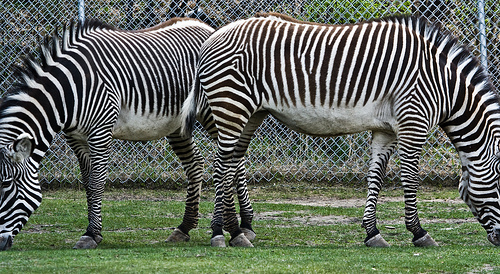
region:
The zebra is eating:
[190, 13, 499, 255]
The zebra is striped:
[187, 7, 497, 270]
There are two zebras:
[1, 1, 498, 269]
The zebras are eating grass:
[3, 3, 499, 272]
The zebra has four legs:
[194, 5, 498, 260]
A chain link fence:
[3, 9, 498, 185]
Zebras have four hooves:
[206, 206, 457, 261]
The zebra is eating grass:
[1, 28, 222, 272]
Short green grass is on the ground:
[7, 185, 496, 267]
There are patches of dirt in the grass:
[254, 177, 351, 270]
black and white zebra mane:
[1, 6, 123, 120]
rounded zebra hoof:
[73, 225, 101, 252]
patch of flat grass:
[274, 238, 348, 265]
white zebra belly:
[256, 88, 384, 152]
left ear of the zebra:
[12, 129, 41, 162]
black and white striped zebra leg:
[200, 106, 240, 248]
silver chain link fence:
[10, 5, 40, 37]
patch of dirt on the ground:
[278, 190, 356, 214]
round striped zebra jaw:
[4, 183, 49, 243]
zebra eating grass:
[0, 2, 242, 254]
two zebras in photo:
[6, 3, 499, 255]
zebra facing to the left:
[2, 132, 54, 254]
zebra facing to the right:
[458, 127, 498, 247]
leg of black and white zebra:
[81, 185, 116, 254]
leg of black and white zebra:
[183, 193, 200, 247]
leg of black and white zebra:
[221, 201, 255, 262]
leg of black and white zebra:
[357, 197, 393, 256]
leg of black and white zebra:
[398, 203, 443, 254]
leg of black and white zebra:
[241, 193, 268, 241]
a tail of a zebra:
[169, 70, 208, 145]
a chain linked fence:
[265, 132, 348, 188]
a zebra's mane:
[385, 11, 498, 133]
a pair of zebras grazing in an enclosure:
[0, 2, 495, 251]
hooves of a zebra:
[151, 220, 310, 260]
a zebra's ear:
[3, 127, 64, 165]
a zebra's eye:
[0, 167, 32, 204]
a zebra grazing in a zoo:
[1, 3, 159, 272]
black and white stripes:
[244, 34, 406, 114]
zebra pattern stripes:
[90, 42, 306, 114]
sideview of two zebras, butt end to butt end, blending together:
[0, 12, 498, 255]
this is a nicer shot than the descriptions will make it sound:
[0, 1, 498, 272]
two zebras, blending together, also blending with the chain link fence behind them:
[3, 1, 499, 257]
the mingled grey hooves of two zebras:
[72, 218, 443, 258]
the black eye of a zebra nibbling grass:
[0, 173, 16, 188]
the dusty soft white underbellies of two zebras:
[101, 100, 396, 142]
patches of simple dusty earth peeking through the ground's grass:
[15, 187, 498, 269]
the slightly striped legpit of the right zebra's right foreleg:
[371, 92, 398, 129]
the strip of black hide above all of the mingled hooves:
[78, 220, 428, 232]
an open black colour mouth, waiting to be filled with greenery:
[0, 231, 14, 249]